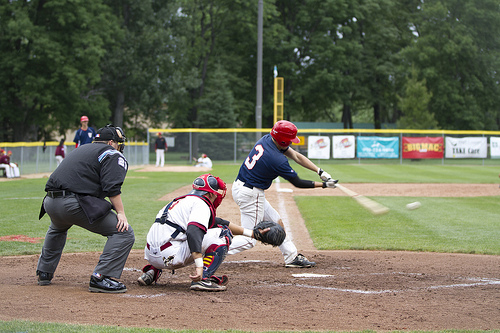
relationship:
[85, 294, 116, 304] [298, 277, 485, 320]
indentations in dirt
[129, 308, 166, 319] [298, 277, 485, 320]
indentations in dirt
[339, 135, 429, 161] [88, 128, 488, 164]
banner on fence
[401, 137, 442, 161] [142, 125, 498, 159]
banner on fence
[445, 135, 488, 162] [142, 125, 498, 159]
banner on fence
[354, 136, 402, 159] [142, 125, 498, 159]
banner on fence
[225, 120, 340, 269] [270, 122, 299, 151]
man wearing helmet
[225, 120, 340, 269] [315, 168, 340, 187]
man wearing gloves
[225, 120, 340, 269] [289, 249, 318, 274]
man wearing shoe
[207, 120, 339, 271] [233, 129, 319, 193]
man wearing shirt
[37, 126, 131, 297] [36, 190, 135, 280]
man wearing pants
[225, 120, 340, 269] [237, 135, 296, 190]
man wearing jersey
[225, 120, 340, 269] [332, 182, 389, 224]
man swinging bat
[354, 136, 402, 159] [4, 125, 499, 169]
banner hanging on fence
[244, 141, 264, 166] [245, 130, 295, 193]
3 on jersey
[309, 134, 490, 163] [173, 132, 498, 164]
advertisements on fence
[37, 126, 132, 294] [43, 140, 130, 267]
man in clothing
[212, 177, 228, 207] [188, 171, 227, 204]
mask on face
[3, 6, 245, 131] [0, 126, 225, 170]
trees behind fence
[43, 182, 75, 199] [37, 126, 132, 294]
belt on man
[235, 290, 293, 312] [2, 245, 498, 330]
indention in dirt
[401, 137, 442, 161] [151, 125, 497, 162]
banner hanging on fence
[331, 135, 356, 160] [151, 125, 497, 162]
banner hanging on fence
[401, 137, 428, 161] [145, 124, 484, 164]
banner hanging on fence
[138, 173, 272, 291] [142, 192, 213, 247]
catcher wearing shirt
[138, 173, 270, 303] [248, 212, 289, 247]
catcher holding mitt